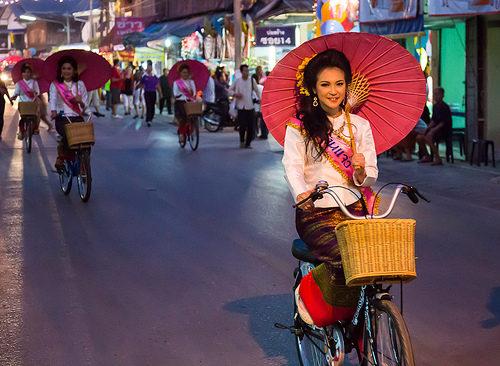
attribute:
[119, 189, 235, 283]
ground — grey, asphalt, flat, sectioned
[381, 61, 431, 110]
umbrella — red, paper, pink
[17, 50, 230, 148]
people — background, walking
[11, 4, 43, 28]
street lamp — on, lit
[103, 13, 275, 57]
building — background, lining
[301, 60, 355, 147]
woman — riding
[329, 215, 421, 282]
basket — brown, woven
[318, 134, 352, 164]
sash — pink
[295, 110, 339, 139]
hair — dark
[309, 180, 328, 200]
bell — silver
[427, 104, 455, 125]
shirt — blue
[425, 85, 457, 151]
person — sitting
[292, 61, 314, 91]
flowers — yellow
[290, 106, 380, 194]
shirt — white